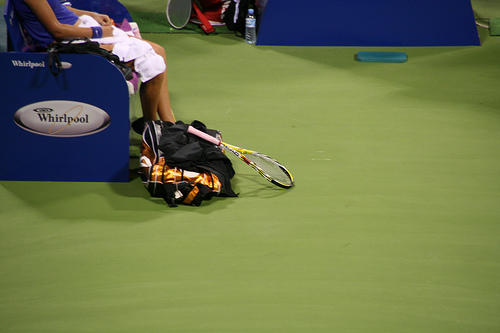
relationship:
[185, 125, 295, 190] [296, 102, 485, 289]
racket on floor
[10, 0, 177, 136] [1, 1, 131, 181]
person sitting on bench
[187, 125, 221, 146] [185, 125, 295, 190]
handle on racket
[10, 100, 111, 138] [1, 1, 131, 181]
ad on bench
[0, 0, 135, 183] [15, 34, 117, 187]
bench for seating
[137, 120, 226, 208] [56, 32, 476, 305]
bag shadow on floor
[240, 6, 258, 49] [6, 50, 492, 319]
bottle on floor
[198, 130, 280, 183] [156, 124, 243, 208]
racket leaning on bag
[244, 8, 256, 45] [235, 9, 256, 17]
bottle with lid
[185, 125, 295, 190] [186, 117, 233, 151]
racket with handle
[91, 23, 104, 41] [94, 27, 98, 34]
blue wristband with white symbol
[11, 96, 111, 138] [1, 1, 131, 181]
symbol on bench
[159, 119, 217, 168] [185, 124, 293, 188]
bag under tennis racket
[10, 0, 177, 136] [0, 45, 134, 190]
person on bench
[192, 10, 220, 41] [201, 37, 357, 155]
strap on ground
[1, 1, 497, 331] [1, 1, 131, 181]
floor with bench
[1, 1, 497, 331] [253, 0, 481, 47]
floor with bench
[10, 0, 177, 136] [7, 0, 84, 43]
person wearing shirt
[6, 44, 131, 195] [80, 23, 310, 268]
bench for people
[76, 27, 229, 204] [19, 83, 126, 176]
person sitting on bench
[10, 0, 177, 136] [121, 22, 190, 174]
person siting with legs crossed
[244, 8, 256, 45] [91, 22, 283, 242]
bottle for people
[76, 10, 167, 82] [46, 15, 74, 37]
towel for wiping sweat